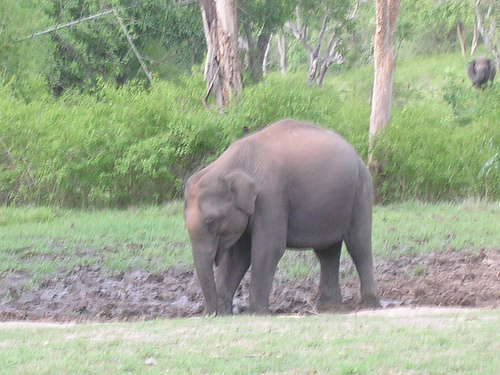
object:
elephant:
[182, 114, 382, 318]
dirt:
[59, 263, 190, 318]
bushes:
[0, 57, 499, 208]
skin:
[250, 150, 311, 201]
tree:
[164, 0, 268, 115]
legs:
[215, 199, 387, 316]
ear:
[226, 168, 260, 214]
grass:
[88, 319, 264, 374]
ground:
[0, 199, 499, 373]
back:
[309, 160, 387, 313]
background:
[0, 0, 500, 374]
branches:
[248, 0, 367, 85]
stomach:
[284, 207, 349, 247]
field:
[0, 201, 500, 374]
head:
[182, 178, 262, 266]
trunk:
[200, 0, 289, 115]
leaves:
[79, 14, 172, 83]